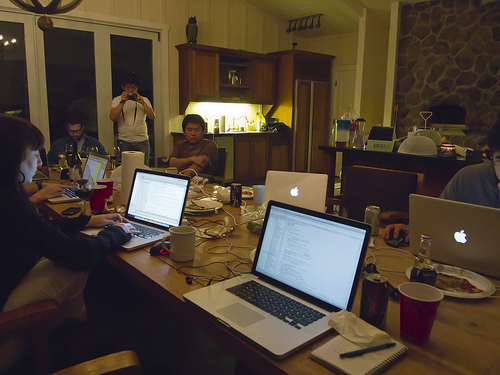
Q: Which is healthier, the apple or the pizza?
A: The apple is healthier than the pizza.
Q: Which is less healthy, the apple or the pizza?
A: The pizza is less healthy than the apple.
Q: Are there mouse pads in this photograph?
A: No, there are no mouse pads.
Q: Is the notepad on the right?
A: Yes, the notepad is on the right of the image.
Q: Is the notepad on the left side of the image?
A: No, the notepad is on the right of the image.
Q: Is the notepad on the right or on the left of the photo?
A: The notepad is on the right of the image.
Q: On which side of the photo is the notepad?
A: The notepad is on the right of the image.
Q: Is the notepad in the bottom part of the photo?
A: Yes, the notepad is in the bottom of the image.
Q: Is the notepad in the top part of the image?
A: No, the notepad is in the bottom of the image.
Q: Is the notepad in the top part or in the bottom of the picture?
A: The notepad is in the bottom of the image.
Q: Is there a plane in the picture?
A: No, there are no airplanes.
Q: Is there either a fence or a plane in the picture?
A: No, there are no airplanes or fences.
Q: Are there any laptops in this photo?
A: Yes, there is a laptop.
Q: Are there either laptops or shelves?
A: Yes, there is a laptop.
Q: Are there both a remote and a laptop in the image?
A: No, there is a laptop but no remote controls.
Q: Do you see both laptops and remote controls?
A: No, there is a laptop but no remote controls.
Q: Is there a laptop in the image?
A: Yes, there is a laptop.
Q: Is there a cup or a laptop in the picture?
A: Yes, there is a laptop.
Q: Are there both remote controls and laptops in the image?
A: No, there is a laptop but no remote controls.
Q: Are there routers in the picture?
A: No, there are no routers.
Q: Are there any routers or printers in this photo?
A: No, there are no routers or printers.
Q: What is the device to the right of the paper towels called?
A: The device is a laptop.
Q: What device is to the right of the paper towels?
A: The device is a laptop.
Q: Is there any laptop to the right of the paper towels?
A: Yes, there is a laptop to the right of the paper towels.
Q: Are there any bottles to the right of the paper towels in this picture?
A: No, there is a laptop to the right of the paper towels.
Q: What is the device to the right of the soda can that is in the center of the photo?
A: The device is a laptop.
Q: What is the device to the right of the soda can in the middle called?
A: The device is a laptop.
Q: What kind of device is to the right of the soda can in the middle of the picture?
A: The device is a laptop.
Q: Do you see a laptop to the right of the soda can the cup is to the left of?
A: Yes, there is a laptop to the right of the soda can.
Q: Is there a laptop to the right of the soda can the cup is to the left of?
A: Yes, there is a laptop to the right of the soda can.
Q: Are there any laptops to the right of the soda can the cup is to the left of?
A: Yes, there is a laptop to the right of the soda can.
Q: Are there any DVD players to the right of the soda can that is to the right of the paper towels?
A: No, there is a laptop to the right of the soda can.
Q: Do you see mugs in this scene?
A: Yes, there is a mug.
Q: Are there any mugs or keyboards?
A: Yes, there is a mug.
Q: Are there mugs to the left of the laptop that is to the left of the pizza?
A: Yes, there is a mug to the left of the laptop.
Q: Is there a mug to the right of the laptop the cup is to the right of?
A: No, the mug is to the left of the laptop computer.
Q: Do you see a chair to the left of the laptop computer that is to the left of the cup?
A: No, there is a mug to the left of the laptop.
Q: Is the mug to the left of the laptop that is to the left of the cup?
A: Yes, the mug is to the left of the laptop computer.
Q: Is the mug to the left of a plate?
A: No, the mug is to the left of the laptop computer.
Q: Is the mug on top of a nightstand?
A: No, the mug is on top of a table.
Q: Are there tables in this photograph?
A: Yes, there is a table.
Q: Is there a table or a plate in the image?
A: Yes, there is a table.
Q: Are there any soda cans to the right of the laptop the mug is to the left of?
A: Yes, there is a soda can to the right of the laptop.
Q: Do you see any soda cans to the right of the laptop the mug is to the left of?
A: Yes, there is a soda can to the right of the laptop.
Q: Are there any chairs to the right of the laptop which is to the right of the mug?
A: No, there is a soda can to the right of the laptop computer.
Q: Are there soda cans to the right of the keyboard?
A: Yes, there is a soda can to the right of the keyboard.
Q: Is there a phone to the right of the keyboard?
A: No, there is a soda can to the right of the keyboard.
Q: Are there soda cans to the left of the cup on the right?
A: Yes, there is a soda can to the left of the cup.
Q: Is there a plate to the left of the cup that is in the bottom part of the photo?
A: No, there is a soda can to the left of the cup.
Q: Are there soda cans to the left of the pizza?
A: Yes, there is a soda can to the left of the pizza.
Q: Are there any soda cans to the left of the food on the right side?
A: Yes, there is a soda can to the left of the pizza.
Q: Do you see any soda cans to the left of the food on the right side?
A: Yes, there is a soda can to the left of the pizza.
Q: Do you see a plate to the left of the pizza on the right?
A: No, there is a soda can to the left of the pizza.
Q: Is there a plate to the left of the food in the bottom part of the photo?
A: No, there is a soda can to the left of the pizza.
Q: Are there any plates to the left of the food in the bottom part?
A: No, there is a soda can to the left of the pizza.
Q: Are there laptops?
A: Yes, there is a laptop.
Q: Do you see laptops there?
A: Yes, there is a laptop.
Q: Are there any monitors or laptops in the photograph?
A: Yes, there is a laptop.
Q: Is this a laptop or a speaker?
A: This is a laptop.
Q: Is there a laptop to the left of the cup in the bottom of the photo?
A: Yes, there is a laptop to the left of the cup.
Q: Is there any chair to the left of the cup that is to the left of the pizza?
A: No, there is a laptop to the left of the cup.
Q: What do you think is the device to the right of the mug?
A: The device is a laptop.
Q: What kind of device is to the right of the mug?
A: The device is a laptop.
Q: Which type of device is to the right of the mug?
A: The device is a laptop.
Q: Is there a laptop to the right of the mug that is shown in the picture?
A: Yes, there is a laptop to the right of the mug.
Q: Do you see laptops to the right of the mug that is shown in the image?
A: Yes, there is a laptop to the right of the mug.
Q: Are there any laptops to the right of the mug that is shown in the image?
A: Yes, there is a laptop to the right of the mug.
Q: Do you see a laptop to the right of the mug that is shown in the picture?
A: Yes, there is a laptop to the right of the mug.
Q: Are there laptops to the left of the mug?
A: No, the laptop is to the right of the mug.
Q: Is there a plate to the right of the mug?
A: No, there is a laptop to the right of the mug.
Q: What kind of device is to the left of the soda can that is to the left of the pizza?
A: The device is a laptop.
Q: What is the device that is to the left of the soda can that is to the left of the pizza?
A: The device is a laptop.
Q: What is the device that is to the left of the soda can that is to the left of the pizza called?
A: The device is a laptop.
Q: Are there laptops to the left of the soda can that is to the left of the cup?
A: Yes, there is a laptop to the left of the soda can.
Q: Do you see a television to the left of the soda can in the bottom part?
A: No, there is a laptop to the left of the soda can.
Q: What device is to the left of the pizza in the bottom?
A: The device is a laptop.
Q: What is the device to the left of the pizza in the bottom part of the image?
A: The device is a laptop.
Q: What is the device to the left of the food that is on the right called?
A: The device is a laptop.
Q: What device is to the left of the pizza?
A: The device is a laptop.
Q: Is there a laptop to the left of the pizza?
A: Yes, there is a laptop to the left of the pizza.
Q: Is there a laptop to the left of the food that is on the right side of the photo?
A: Yes, there is a laptop to the left of the pizza.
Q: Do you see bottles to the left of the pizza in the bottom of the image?
A: No, there is a laptop to the left of the pizza.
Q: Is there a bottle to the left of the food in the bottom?
A: No, there is a laptop to the left of the pizza.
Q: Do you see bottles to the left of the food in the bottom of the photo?
A: No, there is a laptop to the left of the pizza.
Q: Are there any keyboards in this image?
A: Yes, there is a keyboard.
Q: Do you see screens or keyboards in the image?
A: Yes, there is a keyboard.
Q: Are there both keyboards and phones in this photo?
A: No, there is a keyboard but no phones.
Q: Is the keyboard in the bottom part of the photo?
A: Yes, the keyboard is in the bottom of the image.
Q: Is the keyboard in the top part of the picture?
A: No, the keyboard is in the bottom of the image.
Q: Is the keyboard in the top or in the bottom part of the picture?
A: The keyboard is in the bottom of the image.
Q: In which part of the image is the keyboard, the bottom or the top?
A: The keyboard is in the bottom of the image.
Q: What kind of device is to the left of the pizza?
A: The device is a keyboard.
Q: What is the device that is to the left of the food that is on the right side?
A: The device is a keyboard.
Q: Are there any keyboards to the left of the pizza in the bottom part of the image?
A: Yes, there is a keyboard to the left of the pizza.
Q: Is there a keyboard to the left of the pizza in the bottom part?
A: Yes, there is a keyboard to the left of the pizza.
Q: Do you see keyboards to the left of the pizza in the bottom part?
A: Yes, there is a keyboard to the left of the pizza.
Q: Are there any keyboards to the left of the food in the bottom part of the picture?
A: Yes, there is a keyboard to the left of the pizza.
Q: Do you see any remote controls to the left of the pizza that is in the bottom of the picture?
A: No, there is a keyboard to the left of the pizza.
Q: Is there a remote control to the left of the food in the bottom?
A: No, there is a keyboard to the left of the pizza.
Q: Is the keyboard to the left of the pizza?
A: Yes, the keyboard is to the left of the pizza.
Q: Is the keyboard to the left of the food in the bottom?
A: Yes, the keyboard is to the left of the pizza.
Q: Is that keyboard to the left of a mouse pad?
A: No, the keyboard is to the left of the pizza.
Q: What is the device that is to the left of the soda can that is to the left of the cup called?
A: The device is a keyboard.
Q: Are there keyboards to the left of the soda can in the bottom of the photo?
A: Yes, there is a keyboard to the left of the soda can.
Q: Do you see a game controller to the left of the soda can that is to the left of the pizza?
A: No, there is a keyboard to the left of the soda can.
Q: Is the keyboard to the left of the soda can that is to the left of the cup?
A: Yes, the keyboard is to the left of the soda can.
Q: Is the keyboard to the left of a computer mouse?
A: No, the keyboard is to the left of the soda can.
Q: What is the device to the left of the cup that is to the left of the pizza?
A: The device is a keyboard.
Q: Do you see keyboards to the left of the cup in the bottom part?
A: Yes, there is a keyboard to the left of the cup.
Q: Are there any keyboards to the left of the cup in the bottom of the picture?
A: Yes, there is a keyboard to the left of the cup.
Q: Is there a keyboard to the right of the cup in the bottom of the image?
A: No, the keyboard is to the left of the cup.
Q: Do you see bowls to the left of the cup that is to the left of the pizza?
A: No, there is a keyboard to the left of the cup.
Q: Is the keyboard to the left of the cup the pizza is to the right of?
A: Yes, the keyboard is to the left of the cup.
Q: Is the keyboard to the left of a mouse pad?
A: No, the keyboard is to the left of the cup.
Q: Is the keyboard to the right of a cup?
A: No, the keyboard is to the left of a cup.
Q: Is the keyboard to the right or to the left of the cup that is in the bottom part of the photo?
A: The keyboard is to the left of the cup.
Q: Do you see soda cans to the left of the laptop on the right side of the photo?
A: Yes, there is a soda can to the left of the laptop.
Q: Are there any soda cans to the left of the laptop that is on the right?
A: Yes, there is a soda can to the left of the laptop.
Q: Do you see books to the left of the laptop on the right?
A: No, there is a soda can to the left of the laptop.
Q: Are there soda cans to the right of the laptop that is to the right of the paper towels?
A: Yes, there is a soda can to the right of the laptop.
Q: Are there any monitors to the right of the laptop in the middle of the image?
A: No, there is a soda can to the right of the laptop.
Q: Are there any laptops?
A: Yes, there is a laptop.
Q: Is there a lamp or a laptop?
A: Yes, there is a laptop.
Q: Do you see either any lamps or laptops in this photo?
A: Yes, there is a laptop.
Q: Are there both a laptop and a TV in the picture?
A: No, there is a laptop but no televisions.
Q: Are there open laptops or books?
A: Yes, there is an open laptop.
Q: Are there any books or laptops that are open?
A: Yes, the laptop is open.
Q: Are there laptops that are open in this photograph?
A: Yes, there is an open laptop.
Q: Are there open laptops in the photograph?
A: Yes, there is an open laptop.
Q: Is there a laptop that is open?
A: Yes, there is a laptop that is open.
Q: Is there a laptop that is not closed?
A: Yes, there is a open laptop.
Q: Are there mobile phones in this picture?
A: No, there are no mobile phones.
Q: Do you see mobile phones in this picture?
A: No, there are no mobile phones.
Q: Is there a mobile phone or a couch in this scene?
A: No, there are no cell phones or couches.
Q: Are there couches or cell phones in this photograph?
A: No, there are no cell phones or couches.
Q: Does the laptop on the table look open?
A: Yes, the laptop computer is open.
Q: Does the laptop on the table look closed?
A: No, the laptop is open.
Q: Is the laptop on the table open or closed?
A: The laptop is open.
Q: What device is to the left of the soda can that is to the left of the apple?
A: The device is a laptop.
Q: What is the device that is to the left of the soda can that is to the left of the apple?
A: The device is a laptop.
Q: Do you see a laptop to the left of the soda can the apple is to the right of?
A: Yes, there is a laptop to the left of the soda can.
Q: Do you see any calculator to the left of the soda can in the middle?
A: No, there is a laptop to the left of the soda can.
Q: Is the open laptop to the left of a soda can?
A: Yes, the laptop is to the left of a soda can.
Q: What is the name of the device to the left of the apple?
A: The device is a laptop.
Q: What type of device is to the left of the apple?
A: The device is a laptop.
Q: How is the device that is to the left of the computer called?
A: The device is a laptop.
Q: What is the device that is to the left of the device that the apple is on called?
A: The device is a laptop.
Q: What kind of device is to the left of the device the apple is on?
A: The device is a laptop.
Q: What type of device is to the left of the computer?
A: The device is a laptop.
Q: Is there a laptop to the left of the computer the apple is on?
A: Yes, there is a laptop to the left of the computer.